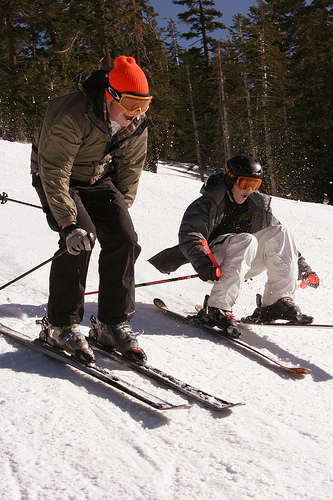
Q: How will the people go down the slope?
A: Skis.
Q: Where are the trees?
A: Background.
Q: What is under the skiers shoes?
A: Skis.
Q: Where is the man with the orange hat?
A: On left.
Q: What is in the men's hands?
A: Poles.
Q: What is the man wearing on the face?
A: Goggles.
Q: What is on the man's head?
A: Helmet.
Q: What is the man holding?
A: Ski poles.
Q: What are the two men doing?
A: Skiing.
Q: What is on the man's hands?
A: Gloves.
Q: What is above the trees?
A: Sky.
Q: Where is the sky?
A: Above trees.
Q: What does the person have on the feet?
A: Skis.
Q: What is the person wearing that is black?
A: Pants.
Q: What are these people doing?
A: Skiing.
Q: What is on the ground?
A: Snow.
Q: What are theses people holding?
A: Ski poles.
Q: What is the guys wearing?
A: Ski pants.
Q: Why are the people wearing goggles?
A: Protect eyes.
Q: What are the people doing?
A: Skiing.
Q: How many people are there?
A: Two.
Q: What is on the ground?
A: Snow.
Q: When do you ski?
A: Winter.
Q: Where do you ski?
A: Mountain.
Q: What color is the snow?
A: White.